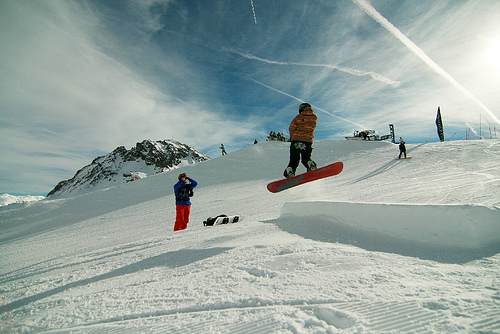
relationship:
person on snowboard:
[281, 94, 322, 177] [261, 160, 346, 196]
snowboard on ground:
[198, 204, 240, 234] [189, 235, 236, 289]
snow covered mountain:
[0, 139, 500, 333] [70, 110, 164, 248]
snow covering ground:
[76, 231, 155, 313] [86, 219, 145, 316]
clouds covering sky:
[35, 35, 124, 108] [181, 46, 271, 116]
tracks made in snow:
[81, 255, 187, 331] [300, 215, 361, 260]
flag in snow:
[425, 88, 462, 166] [344, 260, 367, 276]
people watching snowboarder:
[171, 171, 199, 232] [266, 80, 336, 208]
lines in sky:
[231, 44, 293, 104] [210, 55, 255, 118]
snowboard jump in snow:
[259, 151, 369, 202] [313, 269, 374, 316]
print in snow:
[305, 295, 337, 332] [235, 235, 292, 298]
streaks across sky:
[263, 27, 284, 118] [222, 29, 276, 115]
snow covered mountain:
[110, 155, 129, 172] [75, 130, 171, 183]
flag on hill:
[430, 103, 448, 145] [238, 135, 287, 186]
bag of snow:
[197, 200, 241, 230] [225, 249, 305, 299]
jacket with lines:
[288, 105, 328, 145] [293, 116, 310, 133]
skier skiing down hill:
[213, 134, 236, 165] [232, 139, 260, 203]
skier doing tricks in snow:
[275, 92, 345, 212] [290, 207, 370, 264]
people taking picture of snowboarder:
[171, 171, 199, 232] [272, 87, 357, 226]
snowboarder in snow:
[257, 82, 344, 198] [261, 225, 329, 263]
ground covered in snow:
[195, 240, 340, 320] [267, 263, 305, 305]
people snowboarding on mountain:
[147, 83, 342, 252] [40, 116, 172, 204]